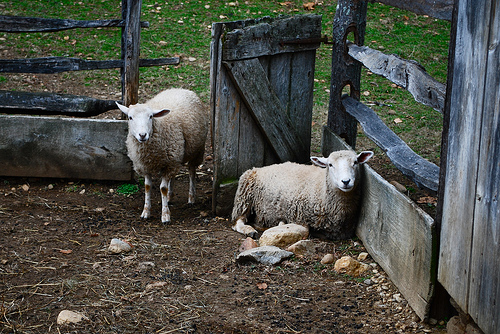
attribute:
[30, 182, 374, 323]
plants — wooden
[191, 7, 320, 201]
door — open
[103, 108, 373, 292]
sheep — laying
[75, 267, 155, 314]
straw — scattered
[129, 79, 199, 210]
sheep — standing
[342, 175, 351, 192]
black nose — of white sheep